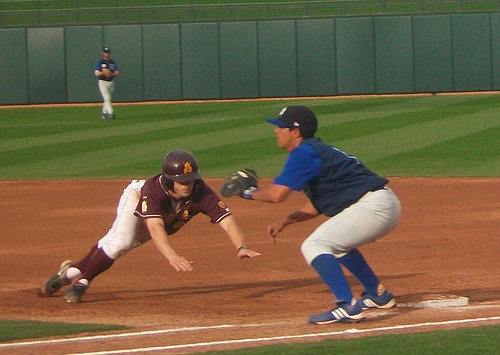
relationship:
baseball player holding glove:
[220, 105, 405, 325] [220, 168, 259, 199]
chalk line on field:
[0, 299, 500, 352] [9, 97, 497, 352]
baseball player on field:
[220, 105, 405, 325] [9, 97, 497, 352]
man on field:
[41, 150, 262, 303] [9, 97, 497, 352]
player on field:
[92, 47, 119, 120] [9, 97, 497, 352]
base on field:
[392, 290, 467, 312] [9, 97, 497, 352]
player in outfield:
[92, 47, 119, 120] [36, 105, 268, 163]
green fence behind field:
[198, 19, 449, 88] [9, 97, 497, 352]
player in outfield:
[92, 47, 119, 120] [4, 80, 499, 164]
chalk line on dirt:
[5, 272, 499, 351] [3, 175, 498, 347]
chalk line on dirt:
[0, 299, 500, 352] [3, 175, 498, 347]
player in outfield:
[92, 41, 117, 116] [8, 98, 497, 210]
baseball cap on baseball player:
[263, 104, 318, 139] [220, 105, 405, 325]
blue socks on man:
[315, 251, 385, 298] [220, 105, 400, 323]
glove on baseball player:
[223, 165, 258, 200] [258, 97, 343, 196]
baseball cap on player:
[263, 100, 320, 140] [196, 90, 403, 325]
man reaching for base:
[41, 150, 262, 303] [392, 291, 469, 312]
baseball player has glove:
[220, 105, 405, 325] [220, 168, 260, 201]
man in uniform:
[34, 146, 265, 310] [62, 151, 232, 285]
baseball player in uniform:
[220, 105, 405, 325] [268, 104, 404, 298]